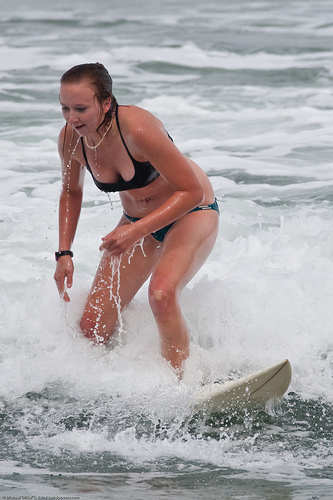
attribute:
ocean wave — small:
[14, 228, 166, 365]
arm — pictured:
[47, 163, 88, 304]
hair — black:
[60, 60, 128, 110]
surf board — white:
[50, 356, 294, 430]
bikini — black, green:
[75, 103, 220, 245]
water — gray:
[2, 1, 331, 244]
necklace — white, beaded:
[81, 130, 112, 153]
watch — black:
[53, 249, 73, 260]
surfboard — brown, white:
[189, 357, 295, 415]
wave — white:
[114, 43, 331, 82]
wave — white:
[5, 274, 329, 392]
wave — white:
[203, 152, 329, 245]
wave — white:
[4, 6, 261, 34]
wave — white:
[2, 124, 56, 198]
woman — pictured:
[52, 61, 220, 378]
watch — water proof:
[54, 248, 74, 259]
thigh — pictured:
[147, 208, 219, 294]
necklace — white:
[85, 122, 112, 148]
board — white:
[144, 351, 303, 426]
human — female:
[31, 48, 221, 390]